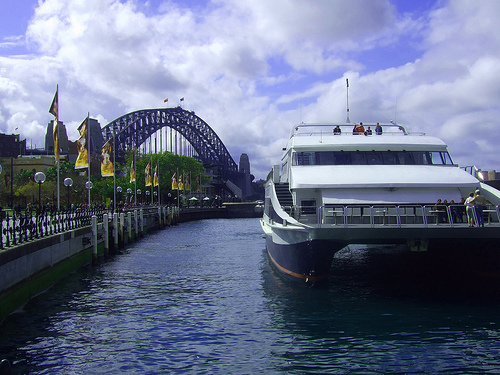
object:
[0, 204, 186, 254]
metal railing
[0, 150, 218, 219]
vegetation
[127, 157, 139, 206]
flag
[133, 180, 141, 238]
pole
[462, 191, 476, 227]
person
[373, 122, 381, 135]
person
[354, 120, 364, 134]
person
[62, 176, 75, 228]
street lighting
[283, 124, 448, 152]
group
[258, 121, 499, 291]
boat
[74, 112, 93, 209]
flag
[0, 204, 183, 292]
bridge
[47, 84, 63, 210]
flag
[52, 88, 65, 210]
pole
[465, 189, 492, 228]
person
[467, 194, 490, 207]
shirt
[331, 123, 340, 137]
people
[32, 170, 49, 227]
lamp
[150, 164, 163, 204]
flag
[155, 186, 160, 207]
pole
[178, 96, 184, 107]
flag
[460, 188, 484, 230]
couple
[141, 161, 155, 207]
flag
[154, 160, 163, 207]
pole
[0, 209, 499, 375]
sea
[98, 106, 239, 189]
bridge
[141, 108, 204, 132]
top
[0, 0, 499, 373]
background